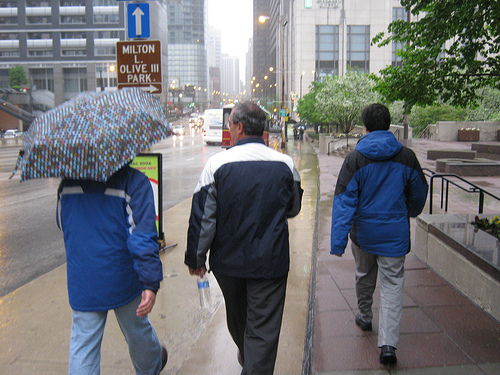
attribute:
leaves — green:
[366, 0, 492, 115]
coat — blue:
[330, 130, 428, 256]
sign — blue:
[104, 14, 166, 48]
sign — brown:
[110, 37, 165, 99]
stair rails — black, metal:
[420, 165, 498, 214]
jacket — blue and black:
[332, 133, 430, 264]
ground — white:
[378, 130, 391, 147]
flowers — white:
[308, 62, 365, 122]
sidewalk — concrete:
[29, 119, 434, 371]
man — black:
[311, 101, 429, 356]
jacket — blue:
[334, 134, 426, 256]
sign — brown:
[104, 37, 179, 103]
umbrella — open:
[7, 84, 178, 184]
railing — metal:
[416, 167, 499, 214]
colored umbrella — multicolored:
[23, 79, 201, 198]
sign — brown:
[115, 40, 163, 96]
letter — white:
[119, 42, 130, 54]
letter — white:
[131, 43, 138, 54]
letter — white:
[141, 42, 147, 54]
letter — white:
[118, 64, 125, 73]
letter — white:
[134, 64, 141, 71]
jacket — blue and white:
[299, 106, 478, 258]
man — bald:
[160, 74, 323, 374]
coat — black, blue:
[324, 128, 433, 260]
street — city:
[2, 126, 313, 362]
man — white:
[182, 93, 311, 373]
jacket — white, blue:
[177, 139, 305, 278]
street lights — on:
[181, 80, 245, 91]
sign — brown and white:
[111, 38, 161, 98]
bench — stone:
[423, 143, 479, 163]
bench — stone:
[434, 153, 497, 185]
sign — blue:
[121, 0, 150, 40]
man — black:
[326, 102, 427, 372]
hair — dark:
[360, 103, 391, 143]